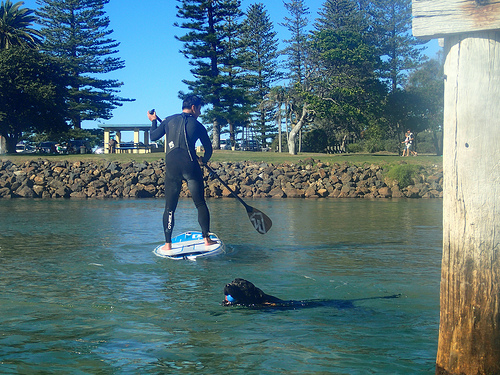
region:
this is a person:
[128, 86, 259, 243]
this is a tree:
[2, 1, 56, 155]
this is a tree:
[34, 5, 122, 145]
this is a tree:
[172, 3, 240, 144]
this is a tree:
[240, 5, 281, 153]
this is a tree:
[281, 3, 323, 140]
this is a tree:
[307, 6, 384, 158]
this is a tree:
[362, 16, 422, 121]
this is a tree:
[368, 66, 432, 150]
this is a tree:
[385, 55, 447, 160]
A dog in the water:
[221, 276, 398, 315]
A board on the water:
[154, 229, 218, 260]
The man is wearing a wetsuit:
[149, 112, 212, 242]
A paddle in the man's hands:
[150, 109, 271, 234]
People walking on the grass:
[403, 129, 415, 158]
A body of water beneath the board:
[0, 198, 442, 374]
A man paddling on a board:
[148, 94, 272, 259]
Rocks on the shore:
[1, 159, 443, 198]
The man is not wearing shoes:
[163, 237, 216, 249]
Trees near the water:
[1, 0, 443, 153]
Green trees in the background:
[6, 5, 130, 120]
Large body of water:
[15, 221, 126, 361]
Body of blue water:
[11, 206, 128, 351]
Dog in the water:
[209, 269, 406, 351]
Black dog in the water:
[206, 266, 405, 344]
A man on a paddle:
[132, 84, 285, 264]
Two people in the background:
[393, 126, 422, 159]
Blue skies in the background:
[127, 22, 169, 73]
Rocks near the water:
[281, 175, 355, 210]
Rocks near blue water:
[287, 171, 352, 215]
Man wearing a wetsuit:
[139, 91, 273, 268]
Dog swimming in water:
[217, 274, 393, 320]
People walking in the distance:
[398, 125, 420, 163]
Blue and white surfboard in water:
[149, 223, 223, 265]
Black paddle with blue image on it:
[205, 163, 276, 238]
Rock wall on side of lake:
[257, 158, 442, 199]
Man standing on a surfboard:
[143, 93, 271, 272]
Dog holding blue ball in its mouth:
[216, 276, 399, 318]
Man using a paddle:
[143, 93, 274, 265]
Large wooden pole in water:
[407, 1, 499, 368]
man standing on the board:
[115, 93, 305, 279]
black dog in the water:
[204, 268, 421, 322]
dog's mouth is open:
[219, 285, 239, 310]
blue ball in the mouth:
[218, 287, 238, 311]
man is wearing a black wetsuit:
[140, 99, 235, 249]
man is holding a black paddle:
[141, 95, 281, 257]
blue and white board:
[139, 212, 238, 269]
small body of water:
[3, 196, 442, 373]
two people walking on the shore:
[394, 126, 423, 158]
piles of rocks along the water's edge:
[2, 158, 459, 203]